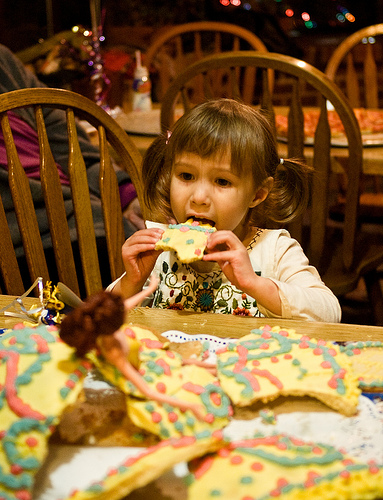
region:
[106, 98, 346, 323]
A little girl eating a cookie.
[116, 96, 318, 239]
A little girl with pigtails.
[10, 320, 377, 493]
A bunch of cookies with red and blue icing.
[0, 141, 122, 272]
A chair with wooden slats.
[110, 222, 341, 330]
A white shirt with decorations.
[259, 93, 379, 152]
A pizza on a platter.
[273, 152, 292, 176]
A white ponytail holder.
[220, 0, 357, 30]
Bright lights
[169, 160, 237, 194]
Two dark eyes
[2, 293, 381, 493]
A wooden table with a bunch of cookies.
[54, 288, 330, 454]
barbie doll with cookie dress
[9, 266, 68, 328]
a knot of ribbons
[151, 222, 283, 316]
a cream crewel worked vest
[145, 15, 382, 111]
rounded top slatted chairs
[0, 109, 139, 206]
a raspberry top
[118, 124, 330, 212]
hair in pig tails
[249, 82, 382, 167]
pizza on next table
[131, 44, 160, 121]
can of soda with a straw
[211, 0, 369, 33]
red lights shine in background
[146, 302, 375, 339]
light wood topped table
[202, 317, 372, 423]
Christmas cookies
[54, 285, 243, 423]
Barbie doll sitting in the cookies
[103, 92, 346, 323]
Little girl eating Christmas cookie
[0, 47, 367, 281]
Brown wooden chairs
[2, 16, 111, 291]
person sitting behind the little girl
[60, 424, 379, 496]
bell shaped cookies with red and green decorations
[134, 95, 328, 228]
little girl with piggy tails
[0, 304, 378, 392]
wooden table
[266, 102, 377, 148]
pizza sitting on a table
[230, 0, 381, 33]
red, blue, and green lights in the background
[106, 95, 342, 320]
the little girl sitting with food to her mouth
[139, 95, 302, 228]
the brown hair on the little girl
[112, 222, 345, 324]
the white top on the girl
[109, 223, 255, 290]
the two hands on the little girl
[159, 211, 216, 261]
the food going into the little girl's mouth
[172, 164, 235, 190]
the little girl's eyes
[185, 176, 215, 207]
the little girl's nose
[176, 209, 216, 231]
the little girl's mouth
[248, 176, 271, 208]
the left ear of the little girl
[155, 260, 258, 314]
the design on the front of the girl's shirt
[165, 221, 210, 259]
girl is eating a cookie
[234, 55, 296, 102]
a brown chair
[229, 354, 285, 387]
decoration on the cookie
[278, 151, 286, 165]
white hair ties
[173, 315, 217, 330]
crumbs on the table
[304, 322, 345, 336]
the table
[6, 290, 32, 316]
ribbon on the table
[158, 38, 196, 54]
a table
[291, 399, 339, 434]
a white cloth on the table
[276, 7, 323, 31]
lights